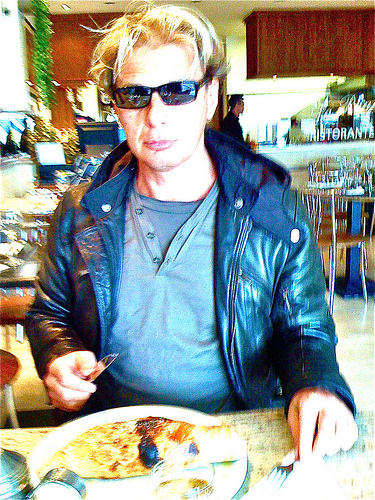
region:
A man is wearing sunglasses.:
[103, 75, 214, 174]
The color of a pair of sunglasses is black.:
[107, 74, 207, 109]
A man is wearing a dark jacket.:
[23, 130, 357, 418]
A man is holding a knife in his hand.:
[38, 345, 119, 410]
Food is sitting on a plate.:
[39, 412, 239, 498]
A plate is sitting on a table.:
[26, 404, 249, 498]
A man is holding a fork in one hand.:
[263, 388, 358, 486]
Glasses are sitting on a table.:
[295, 153, 374, 196]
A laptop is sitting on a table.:
[31, 141, 78, 183]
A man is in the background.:
[213, 90, 253, 154]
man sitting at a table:
[38, 4, 356, 499]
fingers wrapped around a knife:
[41, 346, 113, 414]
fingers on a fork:
[250, 395, 358, 490]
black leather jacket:
[22, 140, 359, 431]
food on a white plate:
[21, 404, 248, 499]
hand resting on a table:
[279, 390, 366, 465]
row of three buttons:
[134, 201, 164, 261]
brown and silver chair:
[301, 188, 369, 312]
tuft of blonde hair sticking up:
[77, 16, 117, 37]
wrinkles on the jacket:
[257, 241, 282, 283]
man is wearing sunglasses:
[145, 86, 196, 105]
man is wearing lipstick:
[140, 127, 184, 153]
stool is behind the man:
[1, 348, 28, 411]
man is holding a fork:
[264, 441, 317, 467]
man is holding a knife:
[84, 356, 104, 382]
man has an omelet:
[64, 430, 102, 469]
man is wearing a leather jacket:
[200, 267, 261, 311]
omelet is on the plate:
[87, 412, 118, 441]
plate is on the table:
[215, 428, 268, 452]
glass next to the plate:
[144, 474, 227, 490]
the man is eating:
[7, 8, 361, 478]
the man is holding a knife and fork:
[5, 322, 341, 496]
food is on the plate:
[9, 391, 252, 495]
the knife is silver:
[24, 351, 145, 404]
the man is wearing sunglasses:
[79, 48, 252, 136]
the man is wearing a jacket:
[5, 153, 359, 409]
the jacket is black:
[22, 137, 363, 418]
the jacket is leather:
[21, 154, 360, 414]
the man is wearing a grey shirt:
[120, 182, 228, 416]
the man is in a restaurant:
[0, 1, 372, 457]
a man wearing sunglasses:
[110, 37, 230, 125]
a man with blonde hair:
[103, 13, 235, 159]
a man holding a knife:
[37, 18, 240, 421]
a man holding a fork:
[130, 21, 322, 489]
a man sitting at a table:
[67, 19, 262, 488]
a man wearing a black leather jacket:
[40, 10, 269, 336]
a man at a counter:
[219, 84, 262, 150]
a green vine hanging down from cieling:
[23, 4, 58, 114]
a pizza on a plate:
[2, 401, 240, 497]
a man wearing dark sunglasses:
[82, 9, 215, 174]